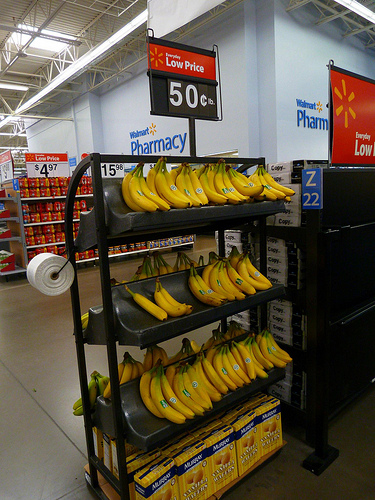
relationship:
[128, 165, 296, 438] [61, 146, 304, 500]
bananas on top of rack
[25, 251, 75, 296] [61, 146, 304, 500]
bags attached to rack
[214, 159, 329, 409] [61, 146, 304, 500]
paper next to rack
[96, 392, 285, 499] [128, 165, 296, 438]
cookies under bananas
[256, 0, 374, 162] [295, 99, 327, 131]
wall with lettering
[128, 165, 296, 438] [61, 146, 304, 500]
bananas resting on rack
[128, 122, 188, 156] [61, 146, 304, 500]
pharmacy sign behind rack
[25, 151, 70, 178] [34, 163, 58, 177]
sign says $4.97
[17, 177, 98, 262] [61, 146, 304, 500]
coffee behind rack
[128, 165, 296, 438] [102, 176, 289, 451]
bananas on top of rack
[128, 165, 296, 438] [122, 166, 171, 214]
bananas in a bunch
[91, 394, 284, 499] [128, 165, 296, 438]
vanilla wafers under bananas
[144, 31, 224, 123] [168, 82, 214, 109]
sign with price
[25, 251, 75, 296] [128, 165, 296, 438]
bags next to bananas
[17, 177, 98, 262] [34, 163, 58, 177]
coffee for $4.97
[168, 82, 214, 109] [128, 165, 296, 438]
price for bananas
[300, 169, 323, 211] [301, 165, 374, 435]
sign for row z22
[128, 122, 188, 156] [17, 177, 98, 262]
pharmacy sign behind coffee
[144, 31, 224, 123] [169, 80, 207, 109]
sign says 50 cents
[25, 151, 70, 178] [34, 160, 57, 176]
sign with price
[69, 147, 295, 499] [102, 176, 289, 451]
products resting on rack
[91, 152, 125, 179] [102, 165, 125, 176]
sign saying $15.98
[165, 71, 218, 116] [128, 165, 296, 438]
price tag for bananas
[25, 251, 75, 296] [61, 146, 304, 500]
bags hanging from rack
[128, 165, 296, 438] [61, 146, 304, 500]
bananas on rack